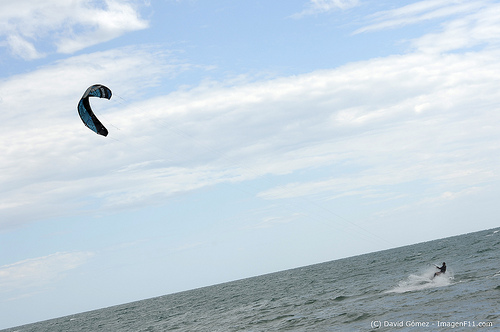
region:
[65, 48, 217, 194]
a parasail in the air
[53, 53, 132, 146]
a blue and black parasail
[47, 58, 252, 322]
a parasail above the water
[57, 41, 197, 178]
a blue and black parasail above the water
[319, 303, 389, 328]
a body of water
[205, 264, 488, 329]
a body of calm water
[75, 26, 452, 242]
a sky that is blue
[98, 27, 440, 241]
a sky that is cloud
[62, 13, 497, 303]
a blue sky with clouds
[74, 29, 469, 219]
a blue sky that is cloudy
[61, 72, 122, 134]
para sail in air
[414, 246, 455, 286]
person parasurfing in ocean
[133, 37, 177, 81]
white clouds in blue sky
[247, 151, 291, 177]
white clouds in blue sky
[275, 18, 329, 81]
white clouds in blue sky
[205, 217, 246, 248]
white clouds in blue sky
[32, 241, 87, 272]
white clouds in blue sky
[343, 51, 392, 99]
white clouds in blue sky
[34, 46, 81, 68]
white clouds in blue sky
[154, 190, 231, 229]
white clouds in blue sky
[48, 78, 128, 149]
para sail in the air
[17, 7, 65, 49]
white clouds in blue sky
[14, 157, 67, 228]
white clouds in blue sky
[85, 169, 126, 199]
white clouds in blue sky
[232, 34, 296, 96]
white clouds in blue sky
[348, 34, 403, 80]
white clouds in blue sky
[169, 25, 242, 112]
white clouds in blue sky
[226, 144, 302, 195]
white clouds in blue sky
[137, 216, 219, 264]
white clouds in blue sky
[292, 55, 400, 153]
white clouds in blue sky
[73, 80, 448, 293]
Man kiteboarding in the ocean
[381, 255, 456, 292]
Spray rising up from the water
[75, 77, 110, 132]
Kite flying in the sky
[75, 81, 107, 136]
Black and blue pattern on kite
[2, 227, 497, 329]
Horizon showing in the distance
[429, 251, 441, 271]
String for kite in man's hand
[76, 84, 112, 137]
Kite flying in curved shape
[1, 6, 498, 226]
White clouds in the distance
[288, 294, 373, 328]
Small waves forming in the water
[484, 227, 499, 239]
Small waves cresting in the background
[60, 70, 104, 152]
black para sail in air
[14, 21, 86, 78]
white clouds in blue sky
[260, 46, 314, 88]
white clouds in blue sky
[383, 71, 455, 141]
white clouds in blue sky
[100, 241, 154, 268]
white clouds in blue sky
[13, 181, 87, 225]
white clouds in blue sky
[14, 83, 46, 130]
white clouds in blue sky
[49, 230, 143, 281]
white clouds in blue sky